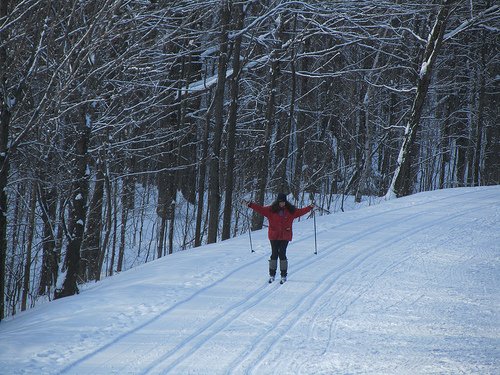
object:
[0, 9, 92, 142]
trees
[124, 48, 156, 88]
branches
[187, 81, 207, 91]
snow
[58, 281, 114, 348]
ground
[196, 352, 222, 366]
white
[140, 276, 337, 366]
street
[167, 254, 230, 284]
snow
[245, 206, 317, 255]
ski poles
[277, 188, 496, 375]
ground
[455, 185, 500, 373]
snow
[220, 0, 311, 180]
trees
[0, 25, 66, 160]
snow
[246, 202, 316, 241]
jacket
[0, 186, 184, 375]
hill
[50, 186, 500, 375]
ski tracks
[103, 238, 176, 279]
snow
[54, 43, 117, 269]
branches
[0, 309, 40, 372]
snow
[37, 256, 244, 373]
slope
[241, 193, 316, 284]
person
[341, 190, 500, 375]
hill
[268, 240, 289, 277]
pants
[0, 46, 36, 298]
branches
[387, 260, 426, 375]
snow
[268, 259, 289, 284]
skis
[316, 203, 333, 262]
snow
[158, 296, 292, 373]
marks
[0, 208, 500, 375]
field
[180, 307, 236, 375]
snow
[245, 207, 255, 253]
pole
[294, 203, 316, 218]
arm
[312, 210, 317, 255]
pole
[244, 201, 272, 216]
arm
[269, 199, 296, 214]
hair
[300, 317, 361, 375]
snow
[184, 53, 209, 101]
branches